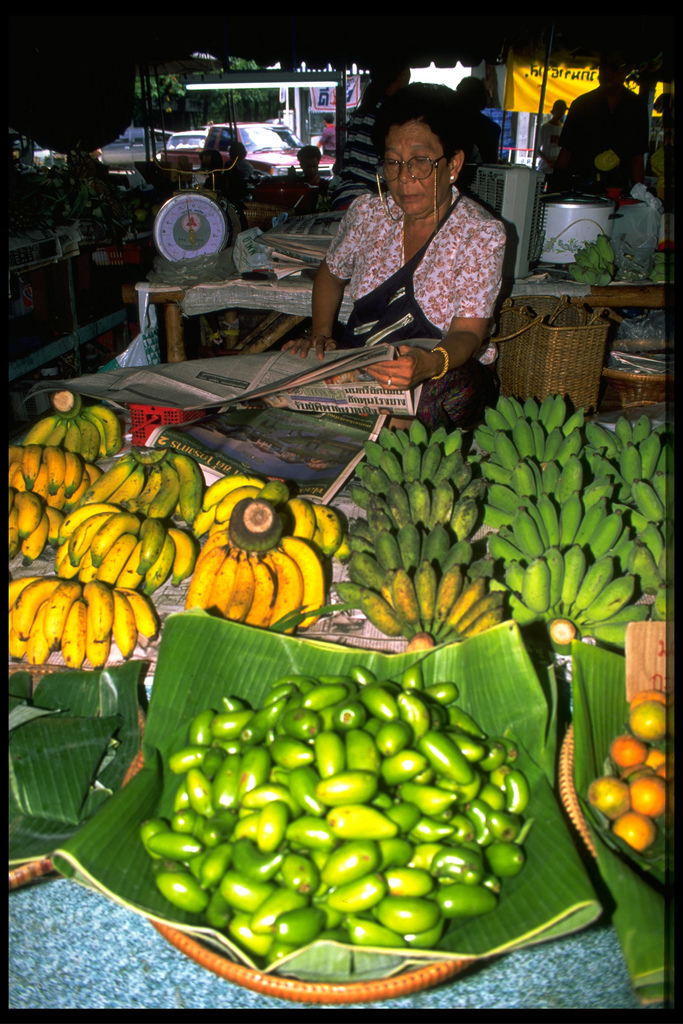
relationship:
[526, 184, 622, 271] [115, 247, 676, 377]
crock pot on shelf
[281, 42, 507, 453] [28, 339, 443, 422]
woman holds newspaper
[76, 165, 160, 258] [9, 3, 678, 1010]
wall on building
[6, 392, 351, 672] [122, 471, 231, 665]
cluster of bananas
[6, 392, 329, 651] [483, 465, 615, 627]
cluster of bananas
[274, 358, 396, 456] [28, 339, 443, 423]
picture in front of newspaper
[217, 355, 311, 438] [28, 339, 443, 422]
tag on newspaper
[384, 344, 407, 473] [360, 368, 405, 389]
ring on finger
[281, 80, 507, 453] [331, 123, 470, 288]
woman won glasses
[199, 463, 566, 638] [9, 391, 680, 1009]
bananas on table